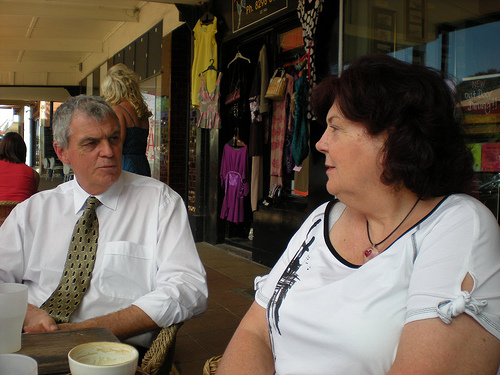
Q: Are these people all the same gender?
A: No, they are both male and female.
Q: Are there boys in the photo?
A: No, there are no boys.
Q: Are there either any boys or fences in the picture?
A: No, there are no boys or fences.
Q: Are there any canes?
A: No, there are no canes.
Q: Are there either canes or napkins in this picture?
A: No, there are no canes or napkins.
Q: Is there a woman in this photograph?
A: Yes, there is a woman.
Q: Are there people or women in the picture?
A: Yes, there is a woman.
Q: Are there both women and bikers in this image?
A: No, there is a woman but no bikers.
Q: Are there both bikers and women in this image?
A: No, there is a woman but no bikers.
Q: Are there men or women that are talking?
A: Yes, the woman is talking.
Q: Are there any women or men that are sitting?
A: Yes, the woman is sitting.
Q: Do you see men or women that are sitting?
A: Yes, the woman is sitting.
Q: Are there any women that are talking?
A: Yes, there is a woman that is talking.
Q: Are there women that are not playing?
A: Yes, there is a woman that is talking.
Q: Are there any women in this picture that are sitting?
A: Yes, there is a woman that is sitting.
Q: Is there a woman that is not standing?
A: Yes, there is a woman that is sitting.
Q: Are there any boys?
A: No, there are no boys.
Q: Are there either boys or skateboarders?
A: No, there are no boys or skateboarders.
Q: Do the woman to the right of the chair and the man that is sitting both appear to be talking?
A: Yes, both the woman and the man are talking.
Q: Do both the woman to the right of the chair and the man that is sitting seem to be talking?
A: Yes, both the woman and the man are talking.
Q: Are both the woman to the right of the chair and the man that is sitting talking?
A: Yes, both the woman and the man are talking.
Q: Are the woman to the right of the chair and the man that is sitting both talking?
A: Yes, both the woman and the man are talking.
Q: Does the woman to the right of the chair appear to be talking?
A: Yes, the woman is talking.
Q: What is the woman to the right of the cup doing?
A: The woman is talking.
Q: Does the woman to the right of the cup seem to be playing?
A: No, the woman is talking.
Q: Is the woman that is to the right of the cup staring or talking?
A: The woman is talking.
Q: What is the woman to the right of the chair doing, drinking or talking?
A: The woman is talking.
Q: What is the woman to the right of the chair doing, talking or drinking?
A: The woman is talking.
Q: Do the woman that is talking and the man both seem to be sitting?
A: Yes, both the woman and the man are sitting.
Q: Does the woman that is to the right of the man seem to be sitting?
A: Yes, the woman is sitting.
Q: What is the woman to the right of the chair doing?
A: The woman is sitting.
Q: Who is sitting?
A: The woman is sitting.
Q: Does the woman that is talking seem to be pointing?
A: No, the woman is sitting.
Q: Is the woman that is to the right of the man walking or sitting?
A: The woman is sitting.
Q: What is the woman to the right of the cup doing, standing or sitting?
A: The woman is sitting.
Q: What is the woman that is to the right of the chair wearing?
A: The woman is wearing a shirt.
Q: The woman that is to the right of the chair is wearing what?
A: The woman is wearing a shirt.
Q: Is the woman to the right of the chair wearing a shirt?
A: Yes, the woman is wearing a shirt.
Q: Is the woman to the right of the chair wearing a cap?
A: No, the woman is wearing a shirt.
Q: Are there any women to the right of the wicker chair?
A: Yes, there is a woman to the right of the chair.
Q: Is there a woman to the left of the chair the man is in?
A: No, the woman is to the right of the chair.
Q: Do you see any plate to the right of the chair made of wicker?
A: No, there is a woman to the right of the chair.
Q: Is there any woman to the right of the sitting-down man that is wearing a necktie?
A: Yes, there is a woman to the right of the man.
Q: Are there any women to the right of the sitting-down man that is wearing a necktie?
A: Yes, there is a woman to the right of the man.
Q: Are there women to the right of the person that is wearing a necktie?
A: Yes, there is a woman to the right of the man.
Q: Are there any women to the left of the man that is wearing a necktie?
A: No, the woman is to the right of the man.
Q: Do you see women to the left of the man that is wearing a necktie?
A: No, the woman is to the right of the man.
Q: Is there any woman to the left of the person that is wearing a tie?
A: No, the woman is to the right of the man.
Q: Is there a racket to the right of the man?
A: No, there is a woman to the right of the man.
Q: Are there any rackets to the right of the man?
A: No, there is a woman to the right of the man.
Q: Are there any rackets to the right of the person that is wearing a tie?
A: No, there is a woman to the right of the man.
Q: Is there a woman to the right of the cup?
A: Yes, there is a woman to the right of the cup.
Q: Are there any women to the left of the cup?
A: No, the woman is to the right of the cup.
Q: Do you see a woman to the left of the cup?
A: No, the woman is to the right of the cup.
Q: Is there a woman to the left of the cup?
A: No, the woman is to the right of the cup.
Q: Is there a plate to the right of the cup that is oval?
A: No, there is a woman to the right of the cup.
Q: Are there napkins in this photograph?
A: No, there are no napkins.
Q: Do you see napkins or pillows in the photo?
A: No, there are no napkins or pillows.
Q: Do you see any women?
A: Yes, there is a woman.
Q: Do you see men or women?
A: Yes, there is a woman.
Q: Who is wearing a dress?
A: The woman is wearing a dress.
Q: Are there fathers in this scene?
A: No, there are no fathers.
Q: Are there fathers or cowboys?
A: No, there are no fathers or cowboys.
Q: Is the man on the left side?
A: Yes, the man is on the left of the image.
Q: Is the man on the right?
A: No, the man is on the left of the image.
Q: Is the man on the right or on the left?
A: The man is on the left of the image.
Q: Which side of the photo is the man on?
A: The man is on the left of the image.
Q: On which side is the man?
A: The man is on the left of the image.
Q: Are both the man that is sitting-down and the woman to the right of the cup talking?
A: Yes, both the man and the woman are talking.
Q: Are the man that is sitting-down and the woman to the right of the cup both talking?
A: Yes, both the man and the woman are talking.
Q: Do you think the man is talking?
A: Yes, the man is talking.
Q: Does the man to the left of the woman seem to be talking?
A: Yes, the man is talking.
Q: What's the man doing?
A: The man is talking.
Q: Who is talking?
A: The man is talking.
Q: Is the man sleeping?
A: No, the man is talking.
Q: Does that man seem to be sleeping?
A: No, the man is talking.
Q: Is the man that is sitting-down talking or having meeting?
A: The man is talking.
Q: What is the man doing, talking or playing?
A: The man is talking.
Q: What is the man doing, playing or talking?
A: The man is talking.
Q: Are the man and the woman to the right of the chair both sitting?
A: Yes, both the man and the woman are sitting.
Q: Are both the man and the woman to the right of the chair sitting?
A: Yes, both the man and the woman are sitting.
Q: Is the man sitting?
A: Yes, the man is sitting.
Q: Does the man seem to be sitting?
A: Yes, the man is sitting.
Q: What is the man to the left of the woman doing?
A: The man is sitting.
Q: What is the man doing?
A: The man is sitting.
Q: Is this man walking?
A: No, the man is sitting.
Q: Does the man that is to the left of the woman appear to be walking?
A: No, the man is sitting.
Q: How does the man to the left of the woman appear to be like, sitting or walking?
A: The man is sitting.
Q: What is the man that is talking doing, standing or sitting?
A: The man is sitting.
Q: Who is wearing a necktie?
A: The man is wearing a necktie.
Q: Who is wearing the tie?
A: The man is wearing a necktie.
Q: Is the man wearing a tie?
A: Yes, the man is wearing a tie.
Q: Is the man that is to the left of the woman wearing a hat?
A: No, the man is wearing a tie.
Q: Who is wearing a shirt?
A: The man is wearing a shirt.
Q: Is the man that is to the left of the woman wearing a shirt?
A: Yes, the man is wearing a shirt.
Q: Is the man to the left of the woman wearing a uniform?
A: No, the man is wearing a shirt.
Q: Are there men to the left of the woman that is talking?
A: Yes, there is a man to the left of the woman.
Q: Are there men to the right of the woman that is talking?
A: No, the man is to the left of the woman.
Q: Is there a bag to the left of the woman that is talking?
A: No, there is a man to the left of the woman.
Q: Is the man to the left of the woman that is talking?
A: Yes, the man is to the left of the woman.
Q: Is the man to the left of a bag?
A: No, the man is to the left of the woman.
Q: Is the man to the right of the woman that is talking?
A: No, the man is to the left of the woman.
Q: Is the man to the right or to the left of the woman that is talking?
A: The man is to the left of the woman.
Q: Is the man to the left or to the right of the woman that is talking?
A: The man is to the left of the woman.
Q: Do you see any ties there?
A: Yes, there is a tie.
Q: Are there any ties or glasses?
A: Yes, there is a tie.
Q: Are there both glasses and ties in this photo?
A: No, there is a tie but no glasses.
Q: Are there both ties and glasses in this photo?
A: No, there is a tie but no glasses.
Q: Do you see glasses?
A: No, there are no glasses.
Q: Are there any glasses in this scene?
A: No, there are no glasses.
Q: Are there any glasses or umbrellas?
A: No, there are no glasses or umbrellas.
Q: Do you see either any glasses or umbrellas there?
A: No, there are no glasses or umbrellas.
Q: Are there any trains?
A: No, there are no trains.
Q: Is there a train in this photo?
A: No, there are no trains.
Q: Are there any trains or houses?
A: No, there are no trains or houses.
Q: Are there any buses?
A: No, there are no buses.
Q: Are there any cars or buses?
A: No, there are no buses or cars.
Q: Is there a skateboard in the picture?
A: No, there are no skateboards.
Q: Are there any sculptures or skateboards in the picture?
A: No, there are no skateboards or sculptures.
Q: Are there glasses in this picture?
A: No, there are no glasses.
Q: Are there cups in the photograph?
A: Yes, there is a cup.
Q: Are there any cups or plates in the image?
A: Yes, there is a cup.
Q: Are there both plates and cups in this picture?
A: No, there is a cup but no plates.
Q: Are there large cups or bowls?
A: Yes, there is a large cup.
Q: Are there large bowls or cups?
A: Yes, there is a large cup.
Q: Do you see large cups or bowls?
A: Yes, there is a large cup.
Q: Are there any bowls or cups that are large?
A: Yes, the cup is large.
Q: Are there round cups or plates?
A: Yes, there is a round cup.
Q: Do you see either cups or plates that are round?
A: Yes, the cup is round.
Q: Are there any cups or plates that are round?
A: Yes, the cup is round.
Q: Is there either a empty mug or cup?
A: Yes, there is an empty cup.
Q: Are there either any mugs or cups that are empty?
A: Yes, the cup is empty.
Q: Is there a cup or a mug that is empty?
A: Yes, the cup is empty.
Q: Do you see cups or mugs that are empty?
A: Yes, the cup is empty.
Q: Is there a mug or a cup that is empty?
A: Yes, the cup is empty.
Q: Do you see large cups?
A: Yes, there is a large cup.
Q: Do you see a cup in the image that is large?
A: Yes, there is a large cup.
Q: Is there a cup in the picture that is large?
A: Yes, there is a cup that is large.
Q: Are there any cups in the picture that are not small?
A: Yes, there is a large cup.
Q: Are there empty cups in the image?
A: Yes, there is an empty cup.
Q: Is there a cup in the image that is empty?
A: Yes, there is a cup that is empty.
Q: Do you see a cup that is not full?
A: Yes, there is a empty cup.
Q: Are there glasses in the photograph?
A: No, there are no glasses.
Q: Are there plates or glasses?
A: No, there are no glasses or plates.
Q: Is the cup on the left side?
A: Yes, the cup is on the left of the image.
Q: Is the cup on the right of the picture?
A: No, the cup is on the left of the image.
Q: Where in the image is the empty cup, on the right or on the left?
A: The cup is on the left of the image.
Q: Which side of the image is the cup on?
A: The cup is on the left of the image.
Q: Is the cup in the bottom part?
A: Yes, the cup is in the bottom of the image.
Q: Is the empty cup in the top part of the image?
A: No, the cup is in the bottom of the image.